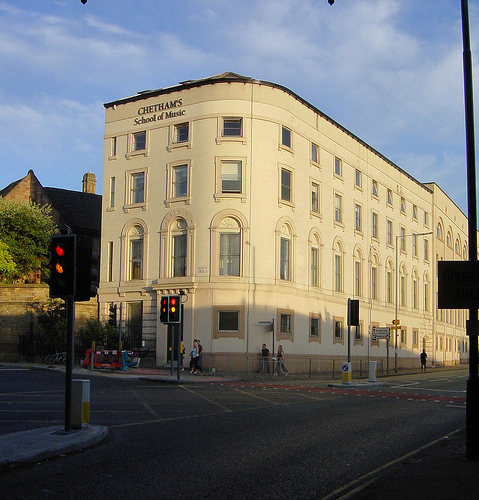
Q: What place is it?
A: It is a street.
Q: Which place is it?
A: It is a street.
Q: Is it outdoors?
A: Yes, it is outdoors.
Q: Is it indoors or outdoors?
A: It is outdoors.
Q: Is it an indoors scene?
A: No, it is outdoors.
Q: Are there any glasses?
A: No, there are no glasses.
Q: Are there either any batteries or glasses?
A: No, there are no glasses or batteries.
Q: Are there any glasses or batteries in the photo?
A: No, there are no glasses or batteries.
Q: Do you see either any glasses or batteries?
A: No, there are no glasses or batteries.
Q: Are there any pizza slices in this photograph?
A: No, there are no pizza slices.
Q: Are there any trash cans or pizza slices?
A: No, there are no pizza slices or trash cans.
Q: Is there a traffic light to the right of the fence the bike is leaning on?
A: Yes, there are traffic lights to the right of the fence.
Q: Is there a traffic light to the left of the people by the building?
A: Yes, there are traffic lights to the left of the people.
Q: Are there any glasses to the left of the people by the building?
A: No, there are traffic lights to the left of the people.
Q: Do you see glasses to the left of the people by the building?
A: No, there are traffic lights to the left of the people.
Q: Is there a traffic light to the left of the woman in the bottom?
A: Yes, there are traffic lights to the left of the woman.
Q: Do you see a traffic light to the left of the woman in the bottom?
A: Yes, there are traffic lights to the left of the woman.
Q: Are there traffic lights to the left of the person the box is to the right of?
A: Yes, there are traffic lights to the left of the woman.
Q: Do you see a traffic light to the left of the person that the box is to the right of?
A: Yes, there are traffic lights to the left of the woman.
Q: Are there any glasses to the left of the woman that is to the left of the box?
A: No, there are traffic lights to the left of the woman.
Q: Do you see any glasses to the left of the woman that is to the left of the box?
A: No, there are traffic lights to the left of the woman.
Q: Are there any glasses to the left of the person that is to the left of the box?
A: No, there are traffic lights to the left of the woman.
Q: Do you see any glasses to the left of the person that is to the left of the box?
A: No, there are traffic lights to the left of the woman.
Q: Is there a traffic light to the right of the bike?
A: Yes, there are traffic lights to the right of the bike.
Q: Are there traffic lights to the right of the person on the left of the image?
A: Yes, there are traffic lights to the right of the person.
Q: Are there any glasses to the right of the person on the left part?
A: No, there are traffic lights to the right of the person.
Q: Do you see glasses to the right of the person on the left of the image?
A: No, there are traffic lights to the right of the person.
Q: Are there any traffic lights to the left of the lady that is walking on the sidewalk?
A: Yes, there are traffic lights to the left of the lady.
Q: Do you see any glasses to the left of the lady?
A: No, there are traffic lights to the left of the lady.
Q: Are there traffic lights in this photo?
A: Yes, there is a traffic light.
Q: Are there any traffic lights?
A: Yes, there is a traffic light.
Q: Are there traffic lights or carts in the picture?
A: Yes, there is a traffic light.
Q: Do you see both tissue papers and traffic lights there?
A: No, there is a traffic light but no tissues.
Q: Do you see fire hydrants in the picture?
A: No, there are no fire hydrants.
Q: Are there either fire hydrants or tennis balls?
A: No, there are no fire hydrants or tennis balls.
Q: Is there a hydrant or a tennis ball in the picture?
A: No, there are no fire hydrants or tennis balls.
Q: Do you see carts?
A: No, there are no carts.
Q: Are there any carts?
A: No, there are no carts.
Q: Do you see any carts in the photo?
A: No, there are no carts.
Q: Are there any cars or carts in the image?
A: No, there are no carts or cars.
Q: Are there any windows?
A: Yes, there is a window.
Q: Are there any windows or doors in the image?
A: Yes, there is a window.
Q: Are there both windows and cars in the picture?
A: No, there is a window but no cars.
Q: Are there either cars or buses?
A: No, there are no cars or buses.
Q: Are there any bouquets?
A: No, there are no bouquets.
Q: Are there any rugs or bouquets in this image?
A: No, there are no bouquets or rugs.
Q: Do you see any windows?
A: Yes, there is a window.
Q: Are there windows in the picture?
A: Yes, there is a window.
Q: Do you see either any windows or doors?
A: Yes, there is a window.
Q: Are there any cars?
A: No, there are no cars.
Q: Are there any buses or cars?
A: No, there are no cars or buses.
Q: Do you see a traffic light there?
A: Yes, there is a traffic light.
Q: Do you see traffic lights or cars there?
A: Yes, there is a traffic light.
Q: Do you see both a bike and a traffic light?
A: Yes, there are both a traffic light and a bike.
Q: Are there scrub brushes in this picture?
A: No, there are no scrub brushes.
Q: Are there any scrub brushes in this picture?
A: No, there are no scrub brushes.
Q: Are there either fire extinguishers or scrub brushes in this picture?
A: No, there are no scrub brushes or fire extinguishers.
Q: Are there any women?
A: Yes, there is a woman.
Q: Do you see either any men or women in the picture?
A: Yes, there is a woman.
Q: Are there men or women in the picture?
A: Yes, there is a woman.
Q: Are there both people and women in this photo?
A: Yes, there are both a woman and a person.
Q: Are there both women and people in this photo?
A: Yes, there are both a woman and a person.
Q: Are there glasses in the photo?
A: No, there are no glasses.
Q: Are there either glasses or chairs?
A: No, there are no glasses or chairs.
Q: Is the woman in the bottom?
A: Yes, the woman is in the bottom of the image.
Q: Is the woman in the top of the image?
A: No, the woman is in the bottom of the image.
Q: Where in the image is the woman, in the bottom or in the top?
A: The woman is in the bottom of the image.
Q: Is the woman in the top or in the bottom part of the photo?
A: The woman is in the bottom of the image.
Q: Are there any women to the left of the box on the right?
A: Yes, there is a woman to the left of the box.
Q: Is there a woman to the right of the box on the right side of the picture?
A: No, the woman is to the left of the box.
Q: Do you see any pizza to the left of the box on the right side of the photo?
A: No, there is a woman to the left of the box.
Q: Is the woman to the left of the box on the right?
A: Yes, the woman is to the left of the box.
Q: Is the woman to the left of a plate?
A: No, the woman is to the left of the box.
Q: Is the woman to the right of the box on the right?
A: No, the woman is to the left of the box.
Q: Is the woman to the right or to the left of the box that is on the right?
A: The woman is to the left of the box.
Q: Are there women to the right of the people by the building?
A: Yes, there is a woman to the right of the people.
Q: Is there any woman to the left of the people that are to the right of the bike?
A: No, the woman is to the right of the people.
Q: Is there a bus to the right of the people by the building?
A: No, there is a woman to the right of the people.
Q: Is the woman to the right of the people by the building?
A: Yes, the woman is to the right of the people.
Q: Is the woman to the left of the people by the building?
A: No, the woman is to the right of the people.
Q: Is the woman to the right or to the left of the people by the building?
A: The woman is to the right of the people.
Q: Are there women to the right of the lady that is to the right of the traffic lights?
A: Yes, there is a woman to the right of the lady.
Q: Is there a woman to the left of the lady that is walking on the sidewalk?
A: No, the woman is to the right of the lady.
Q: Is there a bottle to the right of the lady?
A: No, there is a woman to the right of the lady.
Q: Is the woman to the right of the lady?
A: Yes, the woman is to the right of the lady.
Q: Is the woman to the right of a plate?
A: No, the woman is to the right of the lady.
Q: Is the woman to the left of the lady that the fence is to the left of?
A: No, the woman is to the right of the lady.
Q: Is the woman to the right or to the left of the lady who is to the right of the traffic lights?
A: The woman is to the right of the lady.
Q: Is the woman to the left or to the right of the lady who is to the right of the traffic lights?
A: The woman is to the right of the lady.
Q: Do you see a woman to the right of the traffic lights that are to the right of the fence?
A: Yes, there is a woman to the right of the traffic lights.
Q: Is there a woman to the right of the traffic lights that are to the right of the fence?
A: Yes, there is a woman to the right of the traffic lights.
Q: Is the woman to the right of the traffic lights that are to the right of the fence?
A: Yes, the woman is to the right of the traffic lights.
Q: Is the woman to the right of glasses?
A: No, the woman is to the right of the traffic lights.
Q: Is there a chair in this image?
A: No, there are no chairs.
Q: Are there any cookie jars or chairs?
A: No, there are no chairs or cookie jars.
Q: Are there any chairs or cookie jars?
A: No, there are no chairs or cookie jars.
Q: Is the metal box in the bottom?
A: Yes, the box is in the bottom of the image.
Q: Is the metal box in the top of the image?
A: No, the box is in the bottom of the image.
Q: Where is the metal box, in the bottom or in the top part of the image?
A: The box is in the bottom of the image.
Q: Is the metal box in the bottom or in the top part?
A: The box is in the bottom of the image.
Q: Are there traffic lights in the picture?
A: Yes, there is a traffic light.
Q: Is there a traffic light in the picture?
A: Yes, there is a traffic light.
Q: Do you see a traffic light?
A: Yes, there is a traffic light.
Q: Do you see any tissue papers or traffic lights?
A: Yes, there is a traffic light.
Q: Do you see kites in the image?
A: No, there are no kites.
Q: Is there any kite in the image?
A: No, there are no kites.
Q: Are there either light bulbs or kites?
A: No, there are no kites or light bulbs.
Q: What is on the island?
A: The traffic light is on the island.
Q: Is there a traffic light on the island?
A: Yes, there is a traffic light on the island.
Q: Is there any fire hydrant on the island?
A: No, there is a traffic light on the island.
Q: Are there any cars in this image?
A: No, there are no cars.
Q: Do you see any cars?
A: No, there are no cars.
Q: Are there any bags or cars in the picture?
A: No, there are no cars or bags.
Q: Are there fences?
A: Yes, there is a fence.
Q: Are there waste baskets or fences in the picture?
A: Yes, there is a fence.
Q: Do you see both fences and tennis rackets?
A: No, there is a fence but no rackets.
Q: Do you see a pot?
A: No, there are no pots.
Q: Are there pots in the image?
A: No, there are no pots.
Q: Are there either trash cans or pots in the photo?
A: No, there are no pots or trash cans.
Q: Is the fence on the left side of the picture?
A: Yes, the fence is on the left of the image.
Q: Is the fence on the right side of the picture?
A: No, the fence is on the left of the image.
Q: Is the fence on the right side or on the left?
A: The fence is on the left of the image.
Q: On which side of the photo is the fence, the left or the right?
A: The fence is on the left of the image.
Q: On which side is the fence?
A: The fence is on the left of the image.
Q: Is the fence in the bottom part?
A: Yes, the fence is in the bottom of the image.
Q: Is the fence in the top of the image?
A: No, the fence is in the bottom of the image.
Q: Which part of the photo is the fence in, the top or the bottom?
A: The fence is in the bottom of the image.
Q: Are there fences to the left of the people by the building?
A: Yes, there is a fence to the left of the people.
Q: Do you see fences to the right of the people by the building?
A: No, the fence is to the left of the people.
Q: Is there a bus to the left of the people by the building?
A: No, there is a fence to the left of the people.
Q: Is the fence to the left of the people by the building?
A: Yes, the fence is to the left of the people.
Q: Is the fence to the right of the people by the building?
A: No, the fence is to the left of the people.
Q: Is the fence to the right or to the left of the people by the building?
A: The fence is to the left of the people.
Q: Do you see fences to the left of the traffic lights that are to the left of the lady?
A: Yes, there is a fence to the left of the traffic lights.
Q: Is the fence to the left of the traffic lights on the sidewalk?
A: Yes, the fence is to the left of the traffic lights.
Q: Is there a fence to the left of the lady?
A: Yes, there is a fence to the left of the lady.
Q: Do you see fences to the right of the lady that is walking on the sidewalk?
A: No, the fence is to the left of the lady.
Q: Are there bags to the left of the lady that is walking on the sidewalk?
A: No, there is a fence to the left of the lady.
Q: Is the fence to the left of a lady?
A: Yes, the fence is to the left of a lady.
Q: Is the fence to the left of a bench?
A: No, the fence is to the left of a lady.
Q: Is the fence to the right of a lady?
A: No, the fence is to the left of a lady.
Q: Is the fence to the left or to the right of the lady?
A: The fence is to the left of the lady.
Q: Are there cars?
A: No, there are no cars.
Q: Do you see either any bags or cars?
A: No, there are no cars or bags.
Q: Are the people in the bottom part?
A: Yes, the people are in the bottom of the image.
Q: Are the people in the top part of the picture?
A: No, the people are in the bottom of the image.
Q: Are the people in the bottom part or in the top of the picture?
A: The people are in the bottom of the image.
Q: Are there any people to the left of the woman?
A: Yes, there are people to the left of the woman.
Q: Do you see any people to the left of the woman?
A: Yes, there are people to the left of the woman.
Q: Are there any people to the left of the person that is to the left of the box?
A: Yes, there are people to the left of the woman.